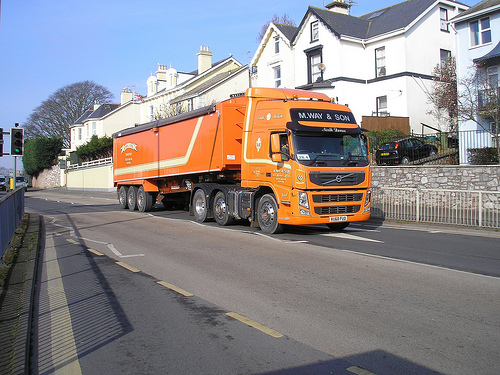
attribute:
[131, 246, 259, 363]
lines — yellow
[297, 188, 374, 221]
headlights — off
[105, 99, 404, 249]
truck — orange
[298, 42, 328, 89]
trim — black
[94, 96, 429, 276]
truck — orange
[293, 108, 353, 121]
letters — white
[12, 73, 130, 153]
trees — bare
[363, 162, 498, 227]
wall — stone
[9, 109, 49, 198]
street light — green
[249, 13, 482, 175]
house — white